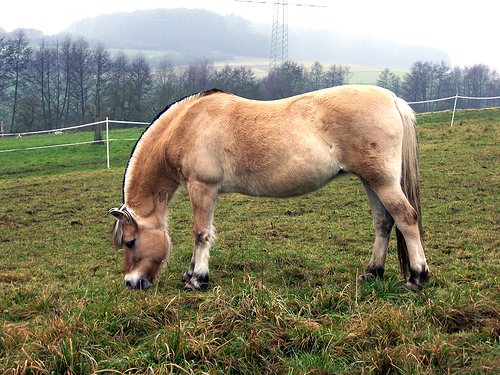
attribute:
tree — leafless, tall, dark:
[88, 57, 119, 106]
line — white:
[46, 101, 123, 162]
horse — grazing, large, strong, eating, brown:
[84, 39, 454, 306]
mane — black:
[152, 79, 203, 122]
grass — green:
[10, 171, 98, 252]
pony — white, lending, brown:
[80, 60, 297, 332]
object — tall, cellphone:
[257, 3, 301, 79]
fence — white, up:
[25, 114, 117, 186]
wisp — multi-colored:
[198, 270, 308, 360]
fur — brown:
[224, 118, 277, 154]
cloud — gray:
[120, 4, 241, 60]